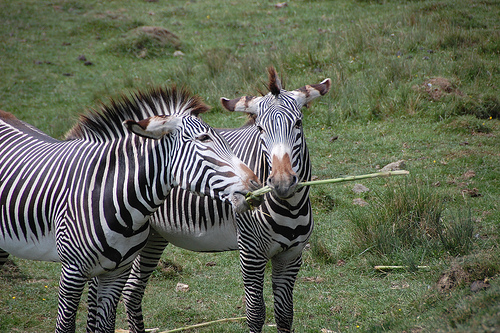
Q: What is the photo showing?
A: It is showing a field.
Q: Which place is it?
A: It is a field.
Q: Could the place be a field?
A: Yes, it is a field.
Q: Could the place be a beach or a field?
A: It is a field.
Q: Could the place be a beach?
A: No, it is a field.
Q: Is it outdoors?
A: Yes, it is outdoors.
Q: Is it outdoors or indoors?
A: It is outdoors.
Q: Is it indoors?
A: No, it is outdoors.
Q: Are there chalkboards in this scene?
A: No, there are no chalkboards.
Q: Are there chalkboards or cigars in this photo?
A: No, there are no chalkboards or cigars.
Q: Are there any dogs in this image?
A: No, there are no dogs.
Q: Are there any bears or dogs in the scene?
A: No, there are no dogs or bears.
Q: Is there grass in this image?
A: Yes, there is grass.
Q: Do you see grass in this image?
A: Yes, there is grass.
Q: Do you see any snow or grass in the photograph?
A: Yes, there is grass.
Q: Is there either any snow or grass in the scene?
A: Yes, there is grass.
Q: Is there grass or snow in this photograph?
A: Yes, there is grass.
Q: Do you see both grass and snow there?
A: No, there is grass but no snow.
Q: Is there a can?
A: No, there are no cans.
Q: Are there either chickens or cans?
A: No, there are no cans or chickens.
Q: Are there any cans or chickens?
A: No, there are no cans or chickens.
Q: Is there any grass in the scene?
A: Yes, there is grass.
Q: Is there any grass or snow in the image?
A: Yes, there is grass.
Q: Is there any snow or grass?
A: Yes, there is grass.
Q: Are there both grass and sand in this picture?
A: No, there is grass but no sand.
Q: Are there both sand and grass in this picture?
A: No, there is grass but no sand.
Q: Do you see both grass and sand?
A: No, there is grass but no sand.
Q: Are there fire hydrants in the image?
A: No, there are no fire hydrants.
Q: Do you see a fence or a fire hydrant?
A: No, there are no fire hydrants or fences.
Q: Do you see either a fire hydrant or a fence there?
A: No, there are no fire hydrants or fences.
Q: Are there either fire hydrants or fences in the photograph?
A: No, there are no fire hydrants or fences.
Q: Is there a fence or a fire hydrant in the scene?
A: No, there are no fire hydrants or fences.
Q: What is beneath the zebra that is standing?
A: The grass is beneath the zebra.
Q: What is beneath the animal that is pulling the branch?
A: The grass is beneath the zebra.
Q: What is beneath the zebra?
A: The grass is beneath the zebra.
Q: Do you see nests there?
A: No, there are no nests.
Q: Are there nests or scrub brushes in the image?
A: No, there are no nests or scrub brushes.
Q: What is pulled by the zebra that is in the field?
A: The branch is pulled by the zebra.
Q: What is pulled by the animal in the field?
A: The branch is pulled by the zebra.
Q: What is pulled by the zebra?
A: The branch is pulled by the zebra.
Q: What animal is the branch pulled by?
A: The branch is pulled by the zebra.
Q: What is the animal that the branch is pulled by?
A: The animal is a zebra.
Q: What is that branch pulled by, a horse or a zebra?
A: The branch is pulled by a zebra.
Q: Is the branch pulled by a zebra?
A: Yes, the branch is pulled by a zebra.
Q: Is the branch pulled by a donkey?
A: No, the branch is pulled by a zebra.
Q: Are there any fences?
A: No, there are no fences.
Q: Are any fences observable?
A: No, there are no fences.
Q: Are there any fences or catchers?
A: No, there are no fences or catchers.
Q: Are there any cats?
A: No, there are no cats.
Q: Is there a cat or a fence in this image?
A: No, there are no cats or fences.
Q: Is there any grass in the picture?
A: Yes, there is grass.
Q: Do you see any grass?
A: Yes, there is grass.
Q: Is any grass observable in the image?
A: Yes, there is grass.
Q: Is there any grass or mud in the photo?
A: Yes, there is grass.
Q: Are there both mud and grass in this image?
A: No, there is grass but no mud.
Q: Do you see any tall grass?
A: Yes, there is tall grass.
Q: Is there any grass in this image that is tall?
A: Yes, there is tall grass.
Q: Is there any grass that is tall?
A: Yes, there is grass that is tall.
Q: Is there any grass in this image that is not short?
A: Yes, there is tall grass.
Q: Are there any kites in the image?
A: No, there are no kites.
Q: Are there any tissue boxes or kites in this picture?
A: No, there are no kites or tissue boxes.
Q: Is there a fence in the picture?
A: No, there are no fences.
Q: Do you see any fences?
A: No, there are no fences.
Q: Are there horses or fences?
A: No, there are no fences or horses.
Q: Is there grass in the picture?
A: Yes, there is grass.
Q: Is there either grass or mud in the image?
A: Yes, there is grass.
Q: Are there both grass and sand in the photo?
A: No, there is grass but no sand.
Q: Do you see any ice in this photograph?
A: No, there is no ice.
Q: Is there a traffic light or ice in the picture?
A: No, there are no ice or traffic lights.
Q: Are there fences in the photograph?
A: No, there are no fences.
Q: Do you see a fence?
A: No, there are no fences.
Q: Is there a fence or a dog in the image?
A: No, there are no fences or dogs.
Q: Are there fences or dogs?
A: No, there are no fences or dogs.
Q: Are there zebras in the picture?
A: Yes, there is a zebra.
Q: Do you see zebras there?
A: Yes, there is a zebra.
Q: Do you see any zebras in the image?
A: Yes, there is a zebra.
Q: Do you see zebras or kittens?
A: Yes, there is a zebra.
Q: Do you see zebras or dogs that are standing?
A: Yes, the zebra is standing.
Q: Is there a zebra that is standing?
A: Yes, there is a zebra that is standing.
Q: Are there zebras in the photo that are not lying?
A: Yes, there is a zebra that is standing.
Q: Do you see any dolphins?
A: No, there are no dolphins.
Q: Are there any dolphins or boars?
A: No, there are no dolphins or boars.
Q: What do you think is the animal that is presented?
A: The animal is a zebra.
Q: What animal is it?
A: The animal is a zebra.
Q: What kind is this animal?
A: This is a zebra.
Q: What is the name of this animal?
A: This is a zebra.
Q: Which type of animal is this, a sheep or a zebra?
A: This is a zebra.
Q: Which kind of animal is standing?
A: The animal is a zebra.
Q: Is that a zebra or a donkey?
A: That is a zebra.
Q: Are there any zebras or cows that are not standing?
A: No, there is a zebra but it is standing.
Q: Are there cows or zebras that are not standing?
A: No, there is a zebra but it is standing.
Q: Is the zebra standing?
A: Yes, the zebra is standing.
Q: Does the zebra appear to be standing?
A: Yes, the zebra is standing.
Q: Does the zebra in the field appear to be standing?
A: Yes, the zebra is standing.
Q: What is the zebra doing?
A: The zebra is standing.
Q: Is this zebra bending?
A: No, the zebra is standing.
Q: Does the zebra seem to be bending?
A: No, the zebra is standing.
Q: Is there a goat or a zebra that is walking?
A: No, there is a zebra but it is standing.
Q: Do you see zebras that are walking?
A: No, there is a zebra but it is standing.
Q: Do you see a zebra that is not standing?
A: No, there is a zebra but it is standing.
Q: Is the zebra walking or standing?
A: The zebra is standing.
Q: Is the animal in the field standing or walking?
A: The zebra is standing.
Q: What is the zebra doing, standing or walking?
A: The zebra is standing.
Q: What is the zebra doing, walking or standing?
A: The zebra is standing.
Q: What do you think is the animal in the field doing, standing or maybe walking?
A: The zebra is standing.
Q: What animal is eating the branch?
A: The zebra is eating the branch.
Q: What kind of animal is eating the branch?
A: The animal is a zebra.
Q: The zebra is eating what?
A: The zebra is eating a branch.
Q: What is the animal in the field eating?
A: The zebra is eating a branch.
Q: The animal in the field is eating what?
A: The zebra is eating a branch.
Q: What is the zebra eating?
A: The zebra is eating a branch.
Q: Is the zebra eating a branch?
A: Yes, the zebra is eating a branch.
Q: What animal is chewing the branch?
A: The zebra is chewing the branch.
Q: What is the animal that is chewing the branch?
A: The animal is a zebra.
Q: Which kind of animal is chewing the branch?
A: The animal is a zebra.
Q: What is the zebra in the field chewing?
A: The zebra is chewing the branch.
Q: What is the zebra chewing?
A: The zebra is chewing the branch.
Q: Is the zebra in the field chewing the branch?
A: Yes, the zebra is chewing the branch.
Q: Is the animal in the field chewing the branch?
A: Yes, the zebra is chewing the branch.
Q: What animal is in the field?
A: The zebra is in the field.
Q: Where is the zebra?
A: The zebra is in the field.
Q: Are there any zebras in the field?
A: Yes, there is a zebra in the field.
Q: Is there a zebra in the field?
A: Yes, there is a zebra in the field.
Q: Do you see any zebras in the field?
A: Yes, there is a zebra in the field.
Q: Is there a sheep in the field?
A: No, there is a zebra in the field.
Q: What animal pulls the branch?
A: The zebra pulls the branch.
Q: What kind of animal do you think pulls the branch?
A: The animal is a zebra.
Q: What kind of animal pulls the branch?
A: The animal is a zebra.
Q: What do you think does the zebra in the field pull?
A: The zebra pulls the branch.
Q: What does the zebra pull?
A: The zebra pulls the branch.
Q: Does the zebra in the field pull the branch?
A: Yes, the zebra pulls the branch.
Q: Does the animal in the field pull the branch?
A: Yes, the zebra pulls the branch.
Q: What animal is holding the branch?
A: The zebra is holding the branch.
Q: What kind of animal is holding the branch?
A: The animal is a zebra.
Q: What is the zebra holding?
A: The zebra is holding the branch.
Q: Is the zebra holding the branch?
A: Yes, the zebra is holding the branch.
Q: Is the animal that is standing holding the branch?
A: Yes, the zebra is holding the branch.